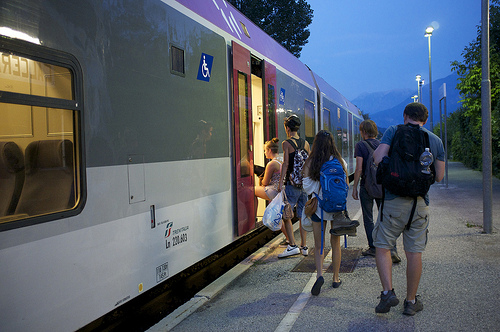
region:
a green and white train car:
[0, 6, 381, 329]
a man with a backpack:
[372, 98, 439, 314]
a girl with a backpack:
[300, 128, 356, 293]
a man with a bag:
[275, 114, 313, 256]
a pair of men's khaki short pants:
[374, 192, 429, 253]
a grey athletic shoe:
[372, 290, 397, 315]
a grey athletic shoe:
[402, 295, 424, 312]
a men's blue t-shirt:
[380, 122, 445, 175]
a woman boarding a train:
[252, 137, 286, 240]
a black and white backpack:
[290, 134, 308, 186]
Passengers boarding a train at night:
[220, 50, 450, 325]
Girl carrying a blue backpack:
[301, 122, 348, 217]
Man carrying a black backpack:
[371, 100, 449, 207]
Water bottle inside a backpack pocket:
[410, 142, 436, 178]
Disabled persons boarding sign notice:
[185, 37, 220, 89]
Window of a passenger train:
[0, 23, 87, 238]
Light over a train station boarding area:
[411, 15, 441, 61]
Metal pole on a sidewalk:
[475, 28, 497, 241]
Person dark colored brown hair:
[393, 98, 433, 124]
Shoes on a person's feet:
[368, 279, 428, 326]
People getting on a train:
[20, 0, 485, 329]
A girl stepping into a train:
[253, 129, 299, 271]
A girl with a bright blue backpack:
[292, 133, 364, 284]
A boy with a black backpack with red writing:
[369, 105, 448, 223]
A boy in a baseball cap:
[272, 110, 314, 234]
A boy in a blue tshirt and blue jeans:
[357, 119, 385, 235]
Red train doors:
[223, 39, 287, 236]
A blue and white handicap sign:
[187, 44, 227, 89]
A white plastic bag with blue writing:
[261, 183, 292, 235]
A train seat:
[4, 124, 87, 236]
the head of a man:
[399, 95, 433, 126]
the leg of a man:
[368, 198, 409, 294]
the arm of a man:
[368, 121, 397, 168]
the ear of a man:
[399, 109, 409, 122]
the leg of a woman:
[311, 205, 330, 281]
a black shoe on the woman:
[328, 273, 347, 291]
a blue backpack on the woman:
[316, 155, 352, 215]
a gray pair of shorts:
[366, 190, 433, 254]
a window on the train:
[0, 32, 90, 228]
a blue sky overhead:
[234, 0, 498, 116]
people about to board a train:
[227, 60, 459, 319]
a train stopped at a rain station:
[31, 4, 498, 325]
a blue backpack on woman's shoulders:
[320, 156, 354, 207]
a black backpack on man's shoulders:
[375, 123, 446, 200]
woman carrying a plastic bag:
[258, 172, 293, 234]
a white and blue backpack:
[288, 143, 311, 183]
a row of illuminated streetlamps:
[387, 18, 449, 101]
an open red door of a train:
[228, 37, 281, 222]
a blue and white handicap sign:
[191, 46, 221, 88]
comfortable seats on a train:
[2, 130, 87, 219]